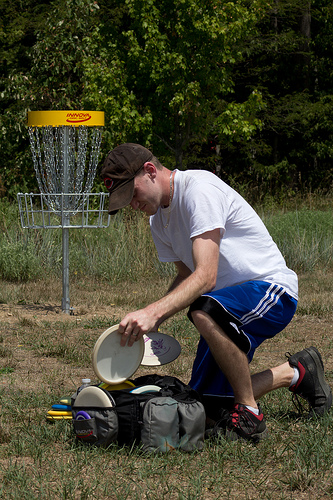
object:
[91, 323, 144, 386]
frisbee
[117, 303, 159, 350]
hand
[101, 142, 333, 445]
man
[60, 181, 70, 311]
pole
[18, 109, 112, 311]
device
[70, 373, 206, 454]
bag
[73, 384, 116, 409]
frisbees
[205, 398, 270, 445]
shoe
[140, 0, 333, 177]
trees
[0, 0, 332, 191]
background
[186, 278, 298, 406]
shorts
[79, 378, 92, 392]
bottle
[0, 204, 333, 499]
grass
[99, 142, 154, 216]
hat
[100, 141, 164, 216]
head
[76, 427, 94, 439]
logo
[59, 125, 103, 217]
chains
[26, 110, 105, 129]
disk catcher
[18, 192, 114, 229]
basket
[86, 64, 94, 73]
leaf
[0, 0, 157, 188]
tree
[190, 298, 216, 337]
knee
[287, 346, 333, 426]
shoe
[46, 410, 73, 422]
frisbee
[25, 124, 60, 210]
chain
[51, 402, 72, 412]
frisbee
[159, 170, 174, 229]
necklace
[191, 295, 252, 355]
trim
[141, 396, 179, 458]
pouch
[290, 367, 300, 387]
socks